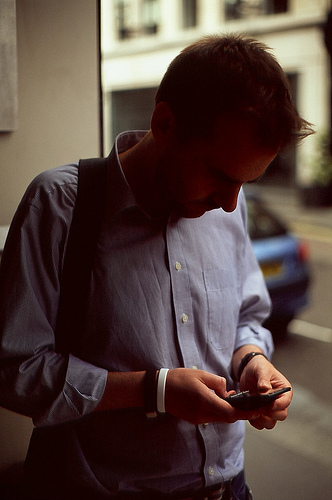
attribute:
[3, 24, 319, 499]
man — looking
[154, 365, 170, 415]
bracelet — white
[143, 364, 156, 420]
bracelet — brown, black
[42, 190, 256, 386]
shirt — blue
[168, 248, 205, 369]
buttons — white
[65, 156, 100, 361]
strap — black, dark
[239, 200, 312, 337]
car — blue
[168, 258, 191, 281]
button — white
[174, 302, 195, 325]
button — white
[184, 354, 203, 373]
button — white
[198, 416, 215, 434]
button — white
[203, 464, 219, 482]
button — white